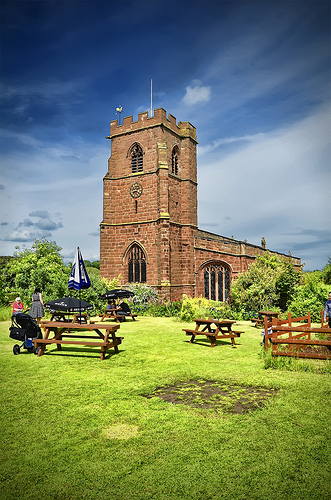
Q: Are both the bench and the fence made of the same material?
A: Yes, both the bench and the fence are made of wood.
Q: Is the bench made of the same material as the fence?
A: Yes, both the bench and the fence are made of wood.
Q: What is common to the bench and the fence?
A: The material, both the bench and the fence are wooden.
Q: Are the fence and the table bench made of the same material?
A: Yes, both the fence and the bench are made of wood.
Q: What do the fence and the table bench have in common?
A: The material, both the fence and the bench are wooden.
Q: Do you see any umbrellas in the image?
A: Yes, there is an umbrella.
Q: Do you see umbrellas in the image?
A: Yes, there is an umbrella.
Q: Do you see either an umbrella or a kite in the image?
A: Yes, there is an umbrella.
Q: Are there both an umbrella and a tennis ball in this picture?
A: No, there is an umbrella but no tennis balls.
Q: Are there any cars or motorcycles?
A: No, there are no cars or motorcycles.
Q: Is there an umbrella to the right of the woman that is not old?
A: Yes, there is an umbrella to the right of the woman.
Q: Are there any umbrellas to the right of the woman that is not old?
A: Yes, there is an umbrella to the right of the woman.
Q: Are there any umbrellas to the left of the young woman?
A: No, the umbrella is to the right of the woman.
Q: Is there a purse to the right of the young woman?
A: No, there is an umbrella to the right of the woman.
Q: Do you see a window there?
A: Yes, there is a window.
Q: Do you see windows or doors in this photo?
A: Yes, there is a window.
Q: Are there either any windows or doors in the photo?
A: Yes, there is a window.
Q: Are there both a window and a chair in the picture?
A: No, there is a window but no chairs.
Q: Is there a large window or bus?
A: Yes, there is a large window.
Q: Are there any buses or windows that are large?
A: Yes, the window is large.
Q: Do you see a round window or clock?
A: Yes, there is a round window.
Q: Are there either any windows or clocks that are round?
A: Yes, the window is round.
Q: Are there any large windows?
A: Yes, there is a large window.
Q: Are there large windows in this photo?
A: Yes, there is a large window.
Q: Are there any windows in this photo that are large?
A: Yes, there is a window that is large.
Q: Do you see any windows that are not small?
A: Yes, there is a large window.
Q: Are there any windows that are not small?
A: Yes, there is a large window.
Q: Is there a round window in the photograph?
A: Yes, there is a round window.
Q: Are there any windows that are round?
A: Yes, there is a window that is round.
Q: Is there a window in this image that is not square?
A: Yes, there is a round window.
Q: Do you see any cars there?
A: No, there are no cars.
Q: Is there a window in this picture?
A: Yes, there is a window.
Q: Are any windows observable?
A: Yes, there is a window.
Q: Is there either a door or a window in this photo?
A: Yes, there is a window.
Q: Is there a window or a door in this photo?
A: Yes, there is a window.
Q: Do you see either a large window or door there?
A: Yes, there is a large window.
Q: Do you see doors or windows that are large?
A: Yes, the window is large.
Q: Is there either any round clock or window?
A: Yes, there is a round window.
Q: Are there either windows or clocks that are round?
A: Yes, the window is round.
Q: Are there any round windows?
A: Yes, there is a round window.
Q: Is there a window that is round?
A: Yes, there is a window that is round.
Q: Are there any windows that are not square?
A: Yes, there is a round window.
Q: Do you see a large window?
A: Yes, there is a large window.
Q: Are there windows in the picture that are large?
A: Yes, there is a window that is large.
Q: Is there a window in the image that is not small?
A: Yes, there is a large window.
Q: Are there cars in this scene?
A: No, there are no cars.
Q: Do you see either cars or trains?
A: No, there are no cars or trains.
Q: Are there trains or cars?
A: No, there are no cars or trains.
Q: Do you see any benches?
A: Yes, there is a bench.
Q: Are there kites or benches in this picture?
A: Yes, there is a bench.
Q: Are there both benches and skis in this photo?
A: No, there is a bench but no skis.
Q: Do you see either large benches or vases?
A: Yes, there is a large bench.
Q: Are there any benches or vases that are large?
A: Yes, the bench is large.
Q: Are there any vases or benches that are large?
A: Yes, the bench is large.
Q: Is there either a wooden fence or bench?
A: Yes, there is a wood bench.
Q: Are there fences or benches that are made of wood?
A: Yes, the bench is made of wood.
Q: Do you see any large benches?
A: Yes, there is a large bench.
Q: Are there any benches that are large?
A: Yes, there is a bench that is large.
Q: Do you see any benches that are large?
A: Yes, there is a bench that is large.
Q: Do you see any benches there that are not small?
A: Yes, there is a large bench.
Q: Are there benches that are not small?
A: Yes, there is a large bench.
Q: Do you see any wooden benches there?
A: Yes, there is a wood bench.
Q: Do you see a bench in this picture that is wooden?
A: Yes, there is a bench that is wooden.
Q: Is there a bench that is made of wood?
A: Yes, there is a bench that is made of wood.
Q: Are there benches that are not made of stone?
A: Yes, there is a bench that is made of wood.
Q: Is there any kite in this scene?
A: No, there are no kites.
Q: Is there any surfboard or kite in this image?
A: No, there are no kites or surfboards.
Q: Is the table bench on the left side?
A: Yes, the bench is on the left of the image.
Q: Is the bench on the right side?
A: No, the bench is on the left of the image.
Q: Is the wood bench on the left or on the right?
A: The bench is on the left of the image.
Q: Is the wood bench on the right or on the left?
A: The bench is on the left of the image.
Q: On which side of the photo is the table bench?
A: The bench is on the left of the image.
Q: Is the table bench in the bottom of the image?
A: Yes, the bench is in the bottom of the image.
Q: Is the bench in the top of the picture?
A: No, the bench is in the bottom of the image.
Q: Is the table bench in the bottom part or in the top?
A: The bench is in the bottom of the image.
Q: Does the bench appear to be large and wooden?
A: Yes, the bench is large and wooden.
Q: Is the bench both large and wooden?
A: Yes, the bench is large and wooden.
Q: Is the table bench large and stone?
A: No, the bench is large but wooden.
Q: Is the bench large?
A: Yes, the bench is large.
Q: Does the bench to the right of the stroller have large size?
A: Yes, the bench is large.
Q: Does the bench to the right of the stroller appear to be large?
A: Yes, the bench is large.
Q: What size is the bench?
A: The bench is large.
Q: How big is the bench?
A: The bench is large.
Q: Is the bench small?
A: No, the bench is large.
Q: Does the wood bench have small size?
A: No, the bench is large.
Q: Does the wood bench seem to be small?
A: No, the bench is large.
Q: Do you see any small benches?
A: No, there is a bench but it is large.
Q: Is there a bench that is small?
A: No, there is a bench but it is large.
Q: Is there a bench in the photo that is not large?
A: No, there is a bench but it is large.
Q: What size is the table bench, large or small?
A: The bench is large.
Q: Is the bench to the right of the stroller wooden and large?
A: Yes, the bench is wooden and large.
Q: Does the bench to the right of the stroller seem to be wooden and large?
A: Yes, the bench is wooden and large.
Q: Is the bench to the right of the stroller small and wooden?
A: No, the bench is wooden but large.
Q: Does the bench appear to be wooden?
A: Yes, the bench is wooden.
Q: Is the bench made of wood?
A: Yes, the bench is made of wood.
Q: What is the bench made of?
A: The bench is made of wood.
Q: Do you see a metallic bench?
A: No, there is a bench but it is wooden.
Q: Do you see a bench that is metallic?
A: No, there is a bench but it is wooden.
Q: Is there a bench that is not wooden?
A: No, there is a bench but it is wooden.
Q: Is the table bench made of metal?
A: No, the bench is made of wood.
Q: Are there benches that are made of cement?
A: No, there is a bench but it is made of wood.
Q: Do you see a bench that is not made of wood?
A: No, there is a bench but it is made of wood.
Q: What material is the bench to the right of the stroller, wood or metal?
A: The bench is made of wood.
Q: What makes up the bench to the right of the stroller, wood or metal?
A: The bench is made of wood.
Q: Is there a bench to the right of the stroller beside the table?
A: Yes, there is a bench to the right of the stroller.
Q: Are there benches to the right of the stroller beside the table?
A: Yes, there is a bench to the right of the stroller.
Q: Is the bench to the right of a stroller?
A: Yes, the bench is to the right of a stroller.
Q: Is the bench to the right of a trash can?
A: No, the bench is to the right of a stroller.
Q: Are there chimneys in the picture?
A: No, there are no chimneys.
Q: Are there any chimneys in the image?
A: No, there are no chimneys.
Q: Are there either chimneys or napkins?
A: No, there are no chimneys or napkins.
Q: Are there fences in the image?
A: Yes, there is a fence.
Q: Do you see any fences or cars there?
A: Yes, there is a fence.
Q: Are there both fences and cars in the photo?
A: No, there is a fence but no cars.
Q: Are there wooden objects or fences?
A: Yes, there is a wood fence.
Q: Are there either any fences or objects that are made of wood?
A: Yes, the fence is made of wood.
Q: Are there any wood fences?
A: Yes, there is a wood fence.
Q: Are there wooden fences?
A: Yes, there is a wood fence.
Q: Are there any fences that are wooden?
A: Yes, there is a fence that is wooden.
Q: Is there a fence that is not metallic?
A: Yes, there is a wooden fence.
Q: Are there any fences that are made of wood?
A: Yes, there is a fence that is made of wood.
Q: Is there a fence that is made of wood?
A: Yes, there is a fence that is made of wood.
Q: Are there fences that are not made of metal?
A: Yes, there is a fence that is made of wood.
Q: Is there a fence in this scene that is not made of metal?
A: Yes, there is a fence that is made of wood.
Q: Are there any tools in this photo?
A: No, there are no tools.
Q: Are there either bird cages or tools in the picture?
A: No, there are no tools or bird cages.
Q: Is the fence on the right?
A: Yes, the fence is on the right of the image.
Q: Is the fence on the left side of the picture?
A: No, the fence is on the right of the image.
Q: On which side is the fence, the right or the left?
A: The fence is on the right of the image.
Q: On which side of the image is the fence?
A: The fence is on the right of the image.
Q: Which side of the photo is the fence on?
A: The fence is on the right of the image.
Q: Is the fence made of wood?
A: Yes, the fence is made of wood.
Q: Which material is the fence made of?
A: The fence is made of wood.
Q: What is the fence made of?
A: The fence is made of wood.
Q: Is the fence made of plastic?
A: No, the fence is made of wood.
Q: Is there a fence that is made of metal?
A: No, there is a fence but it is made of wood.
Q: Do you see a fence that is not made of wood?
A: No, there is a fence but it is made of wood.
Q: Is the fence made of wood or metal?
A: The fence is made of wood.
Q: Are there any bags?
A: No, there are no bags.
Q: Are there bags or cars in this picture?
A: No, there are no bags or cars.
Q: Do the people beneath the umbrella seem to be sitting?
A: Yes, the people are sitting.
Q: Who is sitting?
A: The people are sitting.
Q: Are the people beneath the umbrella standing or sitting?
A: The people are sitting.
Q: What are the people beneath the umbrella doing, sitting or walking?
A: The people are sitting.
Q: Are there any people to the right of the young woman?
A: Yes, there are people to the right of the woman.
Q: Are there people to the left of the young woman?
A: No, the people are to the right of the woman.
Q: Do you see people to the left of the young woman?
A: No, the people are to the right of the woman.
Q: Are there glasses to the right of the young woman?
A: No, there are people to the right of the woman.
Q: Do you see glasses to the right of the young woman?
A: No, there are people to the right of the woman.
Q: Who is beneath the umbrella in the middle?
A: The people are beneath the umbrella.